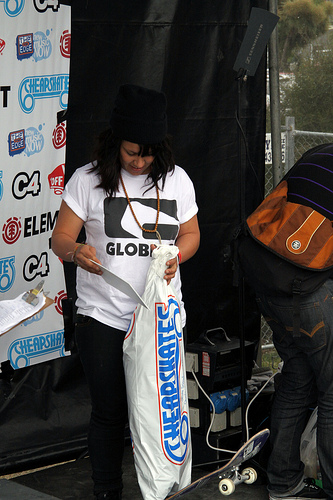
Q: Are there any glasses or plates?
A: No, there are no glasses or plates.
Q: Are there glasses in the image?
A: No, there are no glasses.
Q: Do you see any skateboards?
A: Yes, there is a skateboard.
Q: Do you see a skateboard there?
A: Yes, there is a skateboard.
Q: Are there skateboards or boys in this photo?
A: Yes, there is a skateboard.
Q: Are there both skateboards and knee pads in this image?
A: No, there is a skateboard but no knee pads.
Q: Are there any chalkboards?
A: No, there are no chalkboards.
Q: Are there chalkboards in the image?
A: No, there are no chalkboards.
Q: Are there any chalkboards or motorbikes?
A: No, there are no chalkboards or motorbikes.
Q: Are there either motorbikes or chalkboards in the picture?
A: No, there are no chalkboards or motorbikes.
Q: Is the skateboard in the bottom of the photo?
A: Yes, the skateboard is in the bottom of the image.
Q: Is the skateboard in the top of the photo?
A: No, the skateboard is in the bottom of the image.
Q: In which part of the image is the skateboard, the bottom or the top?
A: The skateboard is in the bottom of the image.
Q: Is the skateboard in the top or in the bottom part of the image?
A: The skateboard is in the bottom of the image.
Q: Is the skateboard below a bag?
A: Yes, the skateboard is below a bag.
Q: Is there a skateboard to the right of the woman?
A: Yes, there is a skateboard to the right of the woman.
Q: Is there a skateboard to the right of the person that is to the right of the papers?
A: Yes, there is a skateboard to the right of the woman.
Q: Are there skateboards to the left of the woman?
A: No, the skateboard is to the right of the woman.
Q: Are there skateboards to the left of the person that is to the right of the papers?
A: No, the skateboard is to the right of the woman.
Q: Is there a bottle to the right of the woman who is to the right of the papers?
A: No, there is a skateboard to the right of the woman.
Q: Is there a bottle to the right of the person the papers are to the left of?
A: No, there is a skateboard to the right of the woman.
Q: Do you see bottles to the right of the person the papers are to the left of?
A: No, there is a skateboard to the right of the woman.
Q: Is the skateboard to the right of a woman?
A: Yes, the skateboard is to the right of a woman.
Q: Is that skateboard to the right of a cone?
A: No, the skateboard is to the right of a woman.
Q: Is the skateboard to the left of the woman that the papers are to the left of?
A: No, the skateboard is to the right of the woman.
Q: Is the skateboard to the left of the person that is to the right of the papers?
A: No, the skateboard is to the right of the woman.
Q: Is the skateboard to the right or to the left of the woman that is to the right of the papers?
A: The skateboard is to the right of the woman.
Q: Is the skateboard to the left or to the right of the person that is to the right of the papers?
A: The skateboard is to the right of the woman.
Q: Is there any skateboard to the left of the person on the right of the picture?
A: Yes, there is a skateboard to the left of the person.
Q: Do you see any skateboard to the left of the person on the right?
A: Yes, there is a skateboard to the left of the person.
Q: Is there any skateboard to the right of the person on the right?
A: No, the skateboard is to the left of the person.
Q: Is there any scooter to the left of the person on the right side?
A: No, there is a skateboard to the left of the person.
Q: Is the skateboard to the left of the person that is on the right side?
A: Yes, the skateboard is to the left of the person.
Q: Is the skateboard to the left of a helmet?
A: No, the skateboard is to the left of the person.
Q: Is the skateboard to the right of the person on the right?
A: No, the skateboard is to the left of the person.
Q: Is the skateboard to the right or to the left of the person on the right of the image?
A: The skateboard is to the left of the person.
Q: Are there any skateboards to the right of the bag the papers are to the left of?
A: Yes, there is a skateboard to the right of the bag.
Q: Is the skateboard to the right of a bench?
A: No, the skateboard is to the right of the bag.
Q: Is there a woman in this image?
A: Yes, there is a woman.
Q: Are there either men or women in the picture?
A: Yes, there is a woman.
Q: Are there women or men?
A: Yes, there is a woman.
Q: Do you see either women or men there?
A: Yes, there is a woman.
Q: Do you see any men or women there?
A: Yes, there is a woman.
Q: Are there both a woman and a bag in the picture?
A: Yes, there are both a woman and a bag.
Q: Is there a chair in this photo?
A: No, there are no chairs.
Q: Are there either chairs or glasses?
A: No, there are no chairs or glasses.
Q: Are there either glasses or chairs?
A: No, there are no chairs or glasses.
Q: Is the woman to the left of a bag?
A: Yes, the woman is to the left of a bag.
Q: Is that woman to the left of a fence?
A: No, the woman is to the left of a bag.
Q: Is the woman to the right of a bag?
A: No, the woman is to the left of a bag.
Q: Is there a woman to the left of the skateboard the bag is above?
A: Yes, there is a woman to the left of the skateboard.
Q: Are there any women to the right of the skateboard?
A: No, the woman is to the left of the skateboard.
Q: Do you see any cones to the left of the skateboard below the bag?
A: No, there is a woman to the left of the skateboard.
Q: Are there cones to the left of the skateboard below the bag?
A: No, there is a woman to the left of the skateboard.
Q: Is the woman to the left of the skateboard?
A: Yes, the woman is to the left of the skateboard.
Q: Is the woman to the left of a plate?
A: No, the woman is to the left of the skateboard.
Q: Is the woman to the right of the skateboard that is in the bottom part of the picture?
A: No, the woman is to the left of the skateboard.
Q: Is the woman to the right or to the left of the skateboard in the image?
A: The woman is to the left of the skateboard.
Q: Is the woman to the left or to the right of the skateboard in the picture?
A: The woman is to the left of the skateboard.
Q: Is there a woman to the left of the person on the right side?
A: Yes, there is a woman to the left of the person.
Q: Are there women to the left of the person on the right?
A: Yes, there is a woman to the left of the person.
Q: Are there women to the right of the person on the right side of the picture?
A: No, the woman is to the left of the person.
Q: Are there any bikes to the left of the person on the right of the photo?
A: No, there is a woman to the left of the person.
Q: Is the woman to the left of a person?
A: Yes, the woman is to the left of a person.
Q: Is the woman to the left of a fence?
A: No, the woman is to the left of a person.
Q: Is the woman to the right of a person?
A: No, the woman is to the left of a person.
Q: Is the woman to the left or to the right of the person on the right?
A: The woman is to the left of the person.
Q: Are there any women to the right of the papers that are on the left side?
A: Yes, there is a woman to the right of the papers.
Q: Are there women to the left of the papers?
A: No, the woman is to the right of the papers.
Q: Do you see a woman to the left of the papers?
A: No, the woman is to the right of the papers.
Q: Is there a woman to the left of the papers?
A: No, the woman is to the right of the papers.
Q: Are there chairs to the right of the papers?
A: No, there is a woman to the right of the papers.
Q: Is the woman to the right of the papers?
A: Yes, the woman is to the right of the papers.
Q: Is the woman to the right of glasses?
A: No, the woman is to the right of the papers.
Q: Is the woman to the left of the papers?
A: No, the woman is to the right of the papers.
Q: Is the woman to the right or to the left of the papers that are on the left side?
A: The woman is to the right of the papers.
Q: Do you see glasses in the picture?
A: No, there are no glasses.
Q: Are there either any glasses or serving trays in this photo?
A: No, there are no glasses or serving trays.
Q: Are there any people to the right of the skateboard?
A: Yes, there is a person to the right of the skateboard.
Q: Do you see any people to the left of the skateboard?
A: No, the person is to the right of the skateboard.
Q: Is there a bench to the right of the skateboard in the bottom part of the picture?
A: No, there is a person to the right of the skateboard.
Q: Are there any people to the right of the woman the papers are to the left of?
A: Yes, there is a person to the right of the woman.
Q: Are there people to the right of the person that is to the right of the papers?
A: Yes, there is a person to the right of the woman.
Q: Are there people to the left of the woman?
A: No, the person is to the right of the woman.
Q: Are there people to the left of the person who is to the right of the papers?
A: No, the person is to the right of the woman.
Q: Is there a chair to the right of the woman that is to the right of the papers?
A: No, there is a person to the right of the woman.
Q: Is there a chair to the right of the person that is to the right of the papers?
A: No, there is a person to the right of the woman.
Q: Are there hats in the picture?
A: Yes, there is a hat.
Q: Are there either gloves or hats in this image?
A: Yes, there is a hat.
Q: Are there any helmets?
A: No, there are no helmets.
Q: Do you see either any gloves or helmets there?
A: No, there are no helmets or gloves.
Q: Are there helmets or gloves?
A: No, there are no helmets or gloves.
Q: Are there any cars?
A: No, there are no cars.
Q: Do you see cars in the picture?
A: No, there are no cars.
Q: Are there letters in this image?
A: Yes, there are letters.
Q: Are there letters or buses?
A: Yes, there are letters.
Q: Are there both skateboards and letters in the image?
A: Yes, there are both letters and a skateboard.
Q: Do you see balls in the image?
A: No, there are no balls.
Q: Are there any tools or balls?
A: No, there are no balls or tools.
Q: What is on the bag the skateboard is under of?
A: The letters are on the bag.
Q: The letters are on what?
A: The letters are on the bag.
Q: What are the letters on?
A: The letters are on the bag.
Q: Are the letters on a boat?
A: No, the letters are on the bag.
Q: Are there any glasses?
A: No, there are no glasses.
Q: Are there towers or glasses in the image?
A: No, there are no glasses or towers.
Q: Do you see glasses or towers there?
A: No, there are no glasses or towers.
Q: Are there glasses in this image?
A: No, there are no glasses.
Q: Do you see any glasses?
A: No, there are no glasses.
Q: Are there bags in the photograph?
A: Yes, there is a bag.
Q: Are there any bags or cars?
A: Yes, there is a bag.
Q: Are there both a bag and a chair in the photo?
A: No, there is a bag but no chairs.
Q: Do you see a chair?
A: No, there are no chairs.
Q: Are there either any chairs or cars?
A: No, there are no chairs or cars.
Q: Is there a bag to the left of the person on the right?
A: Yes, there is a bag to the left of the person.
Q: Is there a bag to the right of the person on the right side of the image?
A: No, the bag is to the left of the person.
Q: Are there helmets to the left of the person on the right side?
A: No, there is a bag to the left of the person.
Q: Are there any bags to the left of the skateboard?
A: Yes, there is a bag to the left of the skateboard.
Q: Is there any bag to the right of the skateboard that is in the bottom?
A: No, the bag is to the left of the skateboard.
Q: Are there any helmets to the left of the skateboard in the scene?
A: No, there is a bag to the left of the skateboard.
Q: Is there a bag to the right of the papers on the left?
A: Yes, there is a bag to the right of the papers.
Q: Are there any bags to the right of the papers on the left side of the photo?
A: Yes, there is a bag to the right of the papers.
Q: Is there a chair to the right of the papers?
A: No, there is a bag to the right of the papers.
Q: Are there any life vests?
A: No, there are no life vests.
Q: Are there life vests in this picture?
A: No, there are no life vests.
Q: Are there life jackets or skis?
A: No, there are no life jackets or skis.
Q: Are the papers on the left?
A: Yes, the papers are on the left of the image.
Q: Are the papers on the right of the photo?
A: No, the papers are on the left of the image.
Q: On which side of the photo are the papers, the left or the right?
A: The papers are on the left of the image.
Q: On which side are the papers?
A: The papers are on the left of the image.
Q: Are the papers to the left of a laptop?
A: No, the papers are to the left of the bag.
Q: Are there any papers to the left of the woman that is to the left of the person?
A: Yes, there are papers to the left of the woman.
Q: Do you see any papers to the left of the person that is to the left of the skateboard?
A: Yes, there are papers to the left of the woman.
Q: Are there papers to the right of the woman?
A: No, the papers are to the left of the woman.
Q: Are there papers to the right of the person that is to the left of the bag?
A: No, the papers are to the left of the woman.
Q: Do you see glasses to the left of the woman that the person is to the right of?
A: No, there are papers to the left of the woman.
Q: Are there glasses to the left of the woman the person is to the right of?
A: No, there are papers to the left of the woman.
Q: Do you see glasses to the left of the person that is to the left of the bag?
A: No, there are papers to the left of the woman.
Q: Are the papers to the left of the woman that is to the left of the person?
A: Yes, the papers are to the left of the woman.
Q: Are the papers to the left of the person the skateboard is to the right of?
A: Yes, the papers are to the left of the woman.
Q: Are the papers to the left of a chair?
A: No, the papers are to the left of the woman.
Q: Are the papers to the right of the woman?
A: No, the papers are to the left of the woman.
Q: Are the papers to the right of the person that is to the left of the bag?
A: No, the papers are to the left of the woman.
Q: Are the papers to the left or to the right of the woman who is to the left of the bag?
A: The papers are to the left of the woman.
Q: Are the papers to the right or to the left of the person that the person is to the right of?
A: The papers are to the left of the woman.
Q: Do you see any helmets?
A: No, there are no helmets.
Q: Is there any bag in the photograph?
A: Yes, there is a bag.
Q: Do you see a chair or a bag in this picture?
A: Yes, there is a bag.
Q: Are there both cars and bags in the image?
A: No, there is a bag but no cars.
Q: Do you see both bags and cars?
A: No, there is a bag but no cars.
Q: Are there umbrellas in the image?
A: No, there are no umbrellas.